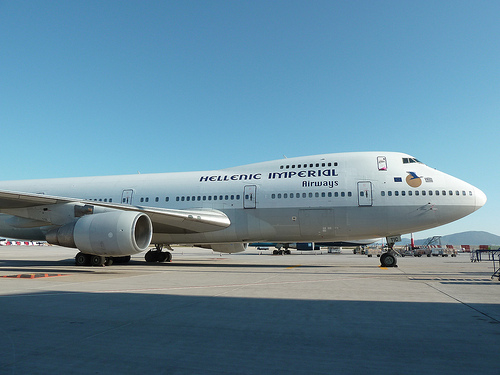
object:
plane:
[0, 147, 487, 267]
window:
[334, 191, 340, 199]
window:
[212, 194, 218, 201]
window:
[164, 195, 170, 203]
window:
[402, 157, 409, 165]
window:
[191, 195, 197, 202]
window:
[295, 191, 301, 199]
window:
[144, 197, 149, 202]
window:
[197, 195, 202, 203]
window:
[202, 196, 208, 201]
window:
[219, 194, 224, 201]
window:
[230, 194, 236, 201]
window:
[234, 194, 243, 202]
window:
[271, 193, 277, 199]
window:
[276, 191, 283, 199]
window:
[284, 192, 289, 199]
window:
[288, 192, 294, 200]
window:
[301, 192, 306, 198]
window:
[308, 192, 314, 199]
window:
[315, 192, 320, 199]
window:
[321, 192, 327, 199]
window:
[327, 191, 333, 198]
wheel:
[381, 252, 398, 266]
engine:
[43, 210, 152, 258]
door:
[242, 185, 257, 210]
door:
[357, 181, 374, 208]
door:
[121, 189, 134, 203]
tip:
[410, 156, 487, 231]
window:
[224, 194, 230, 201]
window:
[201, 194, 208, 202]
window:
[186, 194, 191, 202]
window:
[181, 196, 186, 201]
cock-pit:
[375, 151, 422, 180]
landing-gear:
[372, 238, 403, 268]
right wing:
[1, 190, 230, 235]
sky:
[1, 2, 497, 239]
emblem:
[406, 171, 423, 189]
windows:
[467, 190, 474, 197]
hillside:
[400, 229, 499, 251]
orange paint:
[1, 272, 26, 278]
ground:
[0, 246, 500, 375]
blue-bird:
[406, 171, 423, 181]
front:
[276, 150, 487, 244]